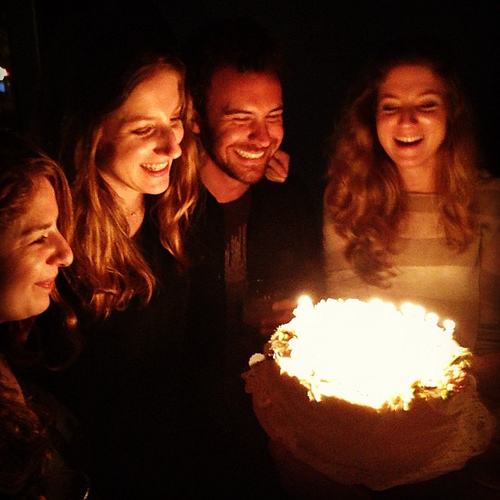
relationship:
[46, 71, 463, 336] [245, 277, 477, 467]
people around cake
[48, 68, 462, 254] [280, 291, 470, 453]
faces around cake